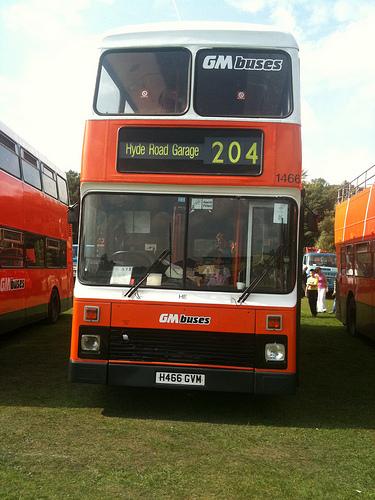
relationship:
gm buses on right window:
[205, 51, 285, 75] [195, 47, 295, 119]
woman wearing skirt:
[314, 261, 332, 314] [316, 285, 328, 317]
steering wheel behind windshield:
[109, 243, 151, 271] [75, 189, 302, 299]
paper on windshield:
[267, 200, 293, 227] [75, 189, 302, 299]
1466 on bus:
[274, 169, 303, 190] [62, 25, 311, 406]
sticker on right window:
[236, 89, 247, 105] [195, 47, 295, 119]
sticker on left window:
[137, 87, 151, 101] [95, 47, 190, 116]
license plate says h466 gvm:
[150, 367, 208, 390] [159, 374, 200, 384]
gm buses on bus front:
[157, 310, 214, 331] [73, 299, 298, 383]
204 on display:
[207, 140, 261, 169] [114, 124, 265, 177]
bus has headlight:
[62, 25, 311, 406] [260, 340, 286, 363]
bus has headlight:
[62, 25, 311, 406] [78, 334, 101, 357]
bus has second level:
[62, 25, 311, 406] [82, 27, 305, 130]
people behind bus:
[303, 264, 332, 318] [62, 25, 311, 406]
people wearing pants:
[303, 271, 318, 318] [303, 289, 318, 317]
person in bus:
[203, 223, 237, 272] [62, 25, 311, 406]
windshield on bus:
[75, 189, 302, 299] [62, 25, 311, 406]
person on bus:
[203, 223, 237, 272] [62, 25, 311, 406]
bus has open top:
[329, 159, 374, 352] [327, 162, 374, 209]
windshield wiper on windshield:
[123, 245, 172, 303] [75, 189, 302, 299]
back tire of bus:
[336, 289, 361, 335] [329, 159, 374, 352]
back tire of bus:
[45, 282, 65, 328] [1, 119, 78, 350]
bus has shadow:
[62, 25, 311, 406] [105, 383, 300, 428]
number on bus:
[202, 134, 263, 167] [62, 25, 311, 406]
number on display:
[202, 134, 263, 167] [114, 124, 265, 177]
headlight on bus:
[260, 340, 286, 363] [62, 25, 311, 406]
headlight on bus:
[78, 334, 101, 357] [62, 25, 311, 406]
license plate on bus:
[150, 367, 208, 390] [62, 25, 311, 406]